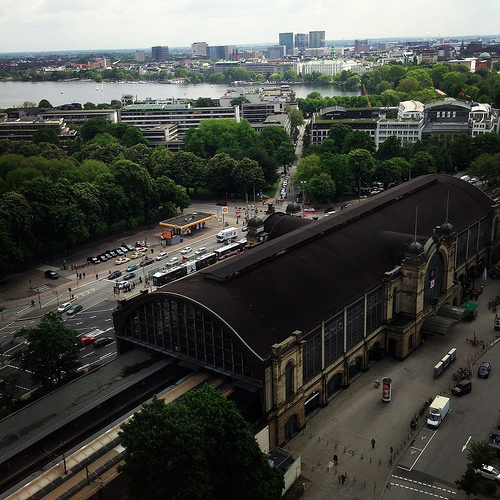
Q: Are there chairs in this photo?
A: No, there are no chairs.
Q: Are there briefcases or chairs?
A: No, there are no chairs or briefcases.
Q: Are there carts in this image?
A: No, there are no carts.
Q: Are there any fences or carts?
A: No, there are no carts or fences.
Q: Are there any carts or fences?
A: No, there are no carts or fences.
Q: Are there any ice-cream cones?
A: No, there are no ice-cream cones.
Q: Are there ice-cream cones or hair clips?
A: No, there are no ice-cream cones or hair clips.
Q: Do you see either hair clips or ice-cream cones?
A: No, there are no ice-cream cones or hair clips.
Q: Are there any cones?
A: No, there are no cones.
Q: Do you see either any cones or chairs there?
A: No, there are no cones or chairs.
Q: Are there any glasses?
A: No, there are no glasses.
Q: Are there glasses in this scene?
A: No, there are no glasses.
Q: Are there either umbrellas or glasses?
A: No, there are no glasses or umbrellas.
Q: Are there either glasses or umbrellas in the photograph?
A: No, there are no glasses or umbrellas.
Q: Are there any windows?
A: Yes, there is a window.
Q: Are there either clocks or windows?
A: Yes, there is a window.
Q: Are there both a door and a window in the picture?
A: No, there is a window but no doors.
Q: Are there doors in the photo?
A: No, there are no doors.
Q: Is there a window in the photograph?
A: Yes, there is a window.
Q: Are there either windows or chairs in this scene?
A: Yes, there is a window.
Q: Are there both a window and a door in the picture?
A: No, there is a window but no doors.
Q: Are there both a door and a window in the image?
A: No, there is a window but no doors.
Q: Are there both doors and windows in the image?
A: No, there is a window but no doors.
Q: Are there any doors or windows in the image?
A: Yes, there is a window.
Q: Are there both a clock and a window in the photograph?
A: No, there is a window but no clocks.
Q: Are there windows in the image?
A: Yes, there is a window.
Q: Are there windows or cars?
A: Yes, there is a window.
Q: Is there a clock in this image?
A: No, there are no clocks.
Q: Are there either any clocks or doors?
A: No, there are no clocks or doors.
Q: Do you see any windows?
A: Yes, there is a window.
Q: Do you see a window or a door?
A: Yes, there is a window.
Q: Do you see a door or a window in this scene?
A: Yes, there is a window.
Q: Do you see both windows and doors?
A: No, there is a window but no doors.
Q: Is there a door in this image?
A: No, there are no doors.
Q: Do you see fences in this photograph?
A: No, there are no fences.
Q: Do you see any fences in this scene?
A: No, there are no fences.